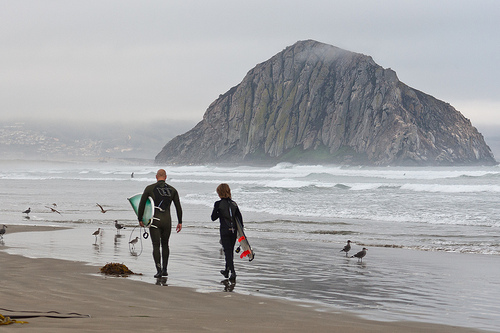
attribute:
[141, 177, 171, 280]
wetsuit — black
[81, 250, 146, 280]
weed — sea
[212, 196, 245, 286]
wetsuits — black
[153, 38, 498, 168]
rock — large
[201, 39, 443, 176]
mountain — gian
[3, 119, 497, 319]
water — large, body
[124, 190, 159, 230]
surfboard — green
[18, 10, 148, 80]
sky — cloud filled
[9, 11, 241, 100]
fog — thick